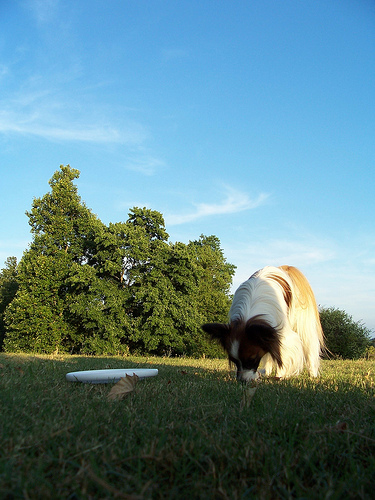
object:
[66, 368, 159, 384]
dog toy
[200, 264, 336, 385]
dog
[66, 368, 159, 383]
frisbee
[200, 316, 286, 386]
head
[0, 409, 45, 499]
grass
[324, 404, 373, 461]
grass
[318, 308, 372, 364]
tree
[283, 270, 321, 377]
light shining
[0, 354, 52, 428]
grass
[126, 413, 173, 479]
grass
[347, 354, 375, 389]
grass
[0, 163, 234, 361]
tree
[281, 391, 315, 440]
grass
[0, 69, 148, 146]
clouds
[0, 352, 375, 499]
ground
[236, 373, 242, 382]
nose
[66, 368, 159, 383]
white frisbee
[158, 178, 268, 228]
cloud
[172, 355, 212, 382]
grass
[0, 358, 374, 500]
shadow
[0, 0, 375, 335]
sky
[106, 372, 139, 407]
leaf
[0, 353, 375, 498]
field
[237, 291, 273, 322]
fur